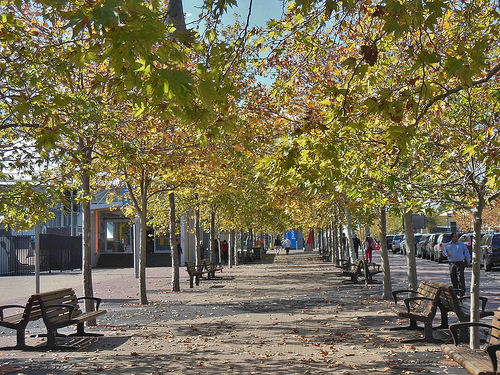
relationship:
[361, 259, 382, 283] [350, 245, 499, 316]
bench on side of road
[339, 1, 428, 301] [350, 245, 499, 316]
tree on side of road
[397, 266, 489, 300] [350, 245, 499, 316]
shadow on road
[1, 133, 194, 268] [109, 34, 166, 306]
buidling behind tree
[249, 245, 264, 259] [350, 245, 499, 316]
table on side of road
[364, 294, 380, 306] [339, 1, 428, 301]
leaf fell from tree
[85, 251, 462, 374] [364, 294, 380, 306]
pavement has leaf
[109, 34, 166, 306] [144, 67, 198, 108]
tree has leaf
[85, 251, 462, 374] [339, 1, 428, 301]
pavement beneath tree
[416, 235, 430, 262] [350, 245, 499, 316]
car on road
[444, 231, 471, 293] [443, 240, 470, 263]
man with a shirt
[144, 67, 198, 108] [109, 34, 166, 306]
leaf on tree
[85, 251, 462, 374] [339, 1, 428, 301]
pavement with tree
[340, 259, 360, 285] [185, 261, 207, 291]
bench facing bench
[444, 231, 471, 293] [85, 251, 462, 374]
man on pavement